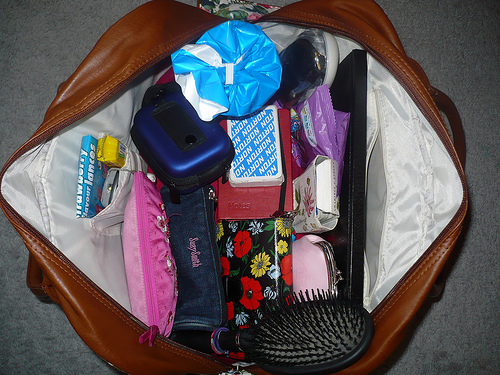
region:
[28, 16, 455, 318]
a lot of stuff in a bag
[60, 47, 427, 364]
this bag if filled with junk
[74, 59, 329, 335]
someone like to travel with many items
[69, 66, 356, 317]
a lot of objects in a bag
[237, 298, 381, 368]
a black brush in the bag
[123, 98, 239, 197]
a blue case in a bag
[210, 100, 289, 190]
a packaged item in the bag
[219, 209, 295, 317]
a flower case in the bag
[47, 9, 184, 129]
the bag is brown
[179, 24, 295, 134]
a light blue object inside of this bag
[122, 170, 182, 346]
small pink pillow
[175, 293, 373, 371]
black hairbrush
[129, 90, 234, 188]
little blue case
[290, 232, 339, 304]
little pink pocketbook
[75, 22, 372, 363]
a bunch of things in brown purse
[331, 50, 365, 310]
black thin tablet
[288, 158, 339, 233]
white cigarrette package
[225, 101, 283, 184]
stack of playing cards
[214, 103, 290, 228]
red case for telephone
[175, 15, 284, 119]
light blue bag of sanitary towels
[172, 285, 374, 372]
black boar bristle hair brush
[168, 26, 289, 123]
blue and white bag in brown case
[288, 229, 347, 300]
pink metal clasp change purse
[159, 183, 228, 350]
long tubular zipper case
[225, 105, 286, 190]
blue and white plastic box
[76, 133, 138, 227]
grey interior pocket in brown bag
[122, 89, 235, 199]
blue and black plastic case in brown leather bag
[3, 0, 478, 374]
open brown leather bag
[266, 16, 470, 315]
brown zipper on brown bag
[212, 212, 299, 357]
floral pattern black case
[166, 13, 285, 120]
blue plastic with white edge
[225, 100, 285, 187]
blue and white playing cards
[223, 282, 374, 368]
blacl hair brush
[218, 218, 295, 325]
red, yellow flowers on black background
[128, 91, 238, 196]
blue and black case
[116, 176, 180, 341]
two toned pink case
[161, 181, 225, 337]
small denim zippered case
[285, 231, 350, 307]
light pink change purse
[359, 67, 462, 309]
pocket in white silky lining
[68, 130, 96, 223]
strawberry flavored gum laces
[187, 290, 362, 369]
A black hairbrush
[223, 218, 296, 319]
A floral wallet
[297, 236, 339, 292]
A small pink coin purse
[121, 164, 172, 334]
A pink pouch that zips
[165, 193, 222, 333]
A denim pouch with pink writing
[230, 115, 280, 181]
A small deck of cards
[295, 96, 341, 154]
A feminine hygiene product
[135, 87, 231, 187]
A blue metal container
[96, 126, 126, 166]
A candy package in a pocket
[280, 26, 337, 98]
An eyeglass case